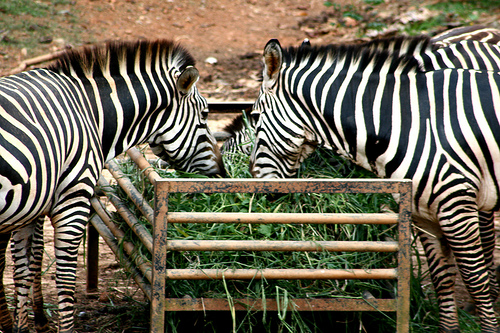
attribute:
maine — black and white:
[68, 34, 258, 75]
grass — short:
[168, 159, 393, 296]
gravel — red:
[146, 7, 324, 59]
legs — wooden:
[82, 209, 104, 292]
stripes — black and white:
[299, 61, 499, 166]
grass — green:
[103, 112, 430, 332]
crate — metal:
[85, 97, 412, 331]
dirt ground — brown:
[86, 3, 381, 101]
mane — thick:
[278, 40, 427, 78]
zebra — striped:
[0, 37, 229, 327]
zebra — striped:
[264, 53, 499, 303]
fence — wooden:
[82, 144, 414, 328]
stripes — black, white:
[354, 58, 432, 178]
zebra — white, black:
[231, 30, 493, 237]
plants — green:
[174, 159, 374, 269]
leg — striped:
[48, 152, 97, 332]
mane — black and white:
[47, 25, 198, 76]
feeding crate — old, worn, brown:
[82, 99, 412, 330]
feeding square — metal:
[84, 99, 413, 330]